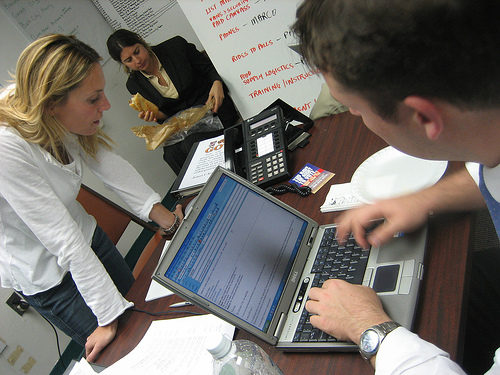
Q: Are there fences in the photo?
A: No, there are no fences.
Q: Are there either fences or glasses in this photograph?
A: No, there are no fences or glasses.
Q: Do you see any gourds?
A: No, there are no gourds.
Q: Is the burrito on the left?
A: Yes, the burrito is on the left of the image.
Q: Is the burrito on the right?
A: No, the burrito is on the left of the image.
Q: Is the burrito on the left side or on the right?
A: The burrito is on the left of the image.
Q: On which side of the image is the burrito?
A: The burrito is on the left of the image.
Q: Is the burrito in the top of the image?
A: Yes, the burrito is in the top of the image.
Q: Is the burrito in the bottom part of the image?
A: No, the burrito is in the top of the image.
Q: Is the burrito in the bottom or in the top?
A: The burrito is in the top of the image.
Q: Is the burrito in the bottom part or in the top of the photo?
A: The burrito is in the top of the image.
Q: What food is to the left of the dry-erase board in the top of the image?
A: The food is a burrito.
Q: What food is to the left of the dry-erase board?
A: The food is a burrito.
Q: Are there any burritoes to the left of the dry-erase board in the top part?
A: Yes, there is a burrito to the left of the dry-erase board.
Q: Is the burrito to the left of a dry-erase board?
A: Yes, the burrito is to the left of a dry-erase board.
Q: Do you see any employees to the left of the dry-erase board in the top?
A: Yes, there is an employee to the left of the dry-erase board.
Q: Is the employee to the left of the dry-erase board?
A: Yes, the employee is to the left of the dry-erase board.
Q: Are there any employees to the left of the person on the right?
A: Yes, there is an employee to the left of the person.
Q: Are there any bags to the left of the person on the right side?
A: No, there is an employee to the left of the person.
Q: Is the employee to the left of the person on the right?
A: Yes, the employee is to the left of the person.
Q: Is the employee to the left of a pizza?
A: No, the employee is to the left of the person.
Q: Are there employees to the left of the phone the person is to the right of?
A: Yes, there is an employee to the left of the telephone.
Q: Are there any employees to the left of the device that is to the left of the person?
A: Yes, there is an employee to the left of the telephone.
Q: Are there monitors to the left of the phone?
A: No, there is an employee to the left of the phone.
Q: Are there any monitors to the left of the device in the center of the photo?
A: No, there is an employee to the left of the phone.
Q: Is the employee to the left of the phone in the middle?
A: Yes, the employee is to the left of the phone.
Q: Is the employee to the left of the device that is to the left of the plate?
A: Yes, the employee is to the left of the phone.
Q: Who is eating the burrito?
A: The employee is eating the burrito.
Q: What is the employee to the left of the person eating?
A: The employee is eating a burrito.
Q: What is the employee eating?
A: The employee is eating a burrito.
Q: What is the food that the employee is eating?
A: The food is a burrito.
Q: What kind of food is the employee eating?
A: The employee is eating a burrito.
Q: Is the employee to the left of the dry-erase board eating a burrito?
A: Yes, the employee is eating a burrito.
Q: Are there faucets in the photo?
A: No, there are no faucets.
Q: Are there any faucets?
A: No, there are no faucets.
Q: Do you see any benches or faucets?
A: No, there are no faucets or benches.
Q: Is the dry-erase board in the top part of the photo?
A: Yes, the dry-erase board is in the top of the image.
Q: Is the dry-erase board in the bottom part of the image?
A: No, the dry-erase board is in the top of the image.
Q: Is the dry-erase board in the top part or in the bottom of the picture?
A: The dry-erase board is in the top of the image.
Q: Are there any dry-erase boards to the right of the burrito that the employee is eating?
A: Yes, there is a dry-erase board to the right of the burrito.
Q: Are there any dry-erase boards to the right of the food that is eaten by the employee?
A: Yes, there is a dry-erase board to the right of the burrito.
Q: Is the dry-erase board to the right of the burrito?
A: Yes, the dry-erase board is to the right of the burrito.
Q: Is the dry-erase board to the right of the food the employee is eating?
A: Yes, the dry-erase board is to the right of the burrito.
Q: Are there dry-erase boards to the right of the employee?
A: Yes, there is a dry-erase board to the right of the employee.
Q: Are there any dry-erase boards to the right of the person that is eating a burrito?
A: Yes, there is a dry-erase board to the right of the employee.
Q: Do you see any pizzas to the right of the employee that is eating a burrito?
A: No, there is a dry-erase board to the right of the employee.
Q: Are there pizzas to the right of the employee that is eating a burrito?
A: No, there is a dry-erase board to the right of the employee.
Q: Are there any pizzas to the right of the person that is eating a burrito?
A: No, there is a dry-erase board to the right of the employee.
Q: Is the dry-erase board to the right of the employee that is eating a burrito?
A: Yes, the dry-erase board is to the right of the employee.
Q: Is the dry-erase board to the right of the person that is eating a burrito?
A: Yes, the dry-erase board is to the right of the employee.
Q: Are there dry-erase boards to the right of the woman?
A: Yes, there is a dry-erase board to the right of the woman.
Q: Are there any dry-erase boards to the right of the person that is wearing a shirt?
A: Yes, there is a dry-erase board to the right of the woman.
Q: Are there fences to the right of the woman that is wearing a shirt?
A: No, there is a dry-erase board to the right of the woman.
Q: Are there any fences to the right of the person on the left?
A: No, there is a dry-erase board to the right of the woman.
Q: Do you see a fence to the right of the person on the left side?
A: No, there is a dry-erase board to the right of the woman.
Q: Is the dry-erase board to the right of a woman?
A: Yes, the dry-erase board is to the right of a woman.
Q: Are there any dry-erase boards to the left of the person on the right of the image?
A: Yes, there is a dry-erase board to the left of the person.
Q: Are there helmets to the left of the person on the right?
A: No, there is a dry-erase board to the left of the person.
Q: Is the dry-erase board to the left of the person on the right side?
A: Yes, the dry-erase board is to the left of the person.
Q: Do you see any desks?
A: Yes, there is a desk.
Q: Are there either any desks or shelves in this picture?
A: Yes, there is a desk.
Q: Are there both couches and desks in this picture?
A: No, there is a desk but no couches.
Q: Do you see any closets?
A: No, there are no closets.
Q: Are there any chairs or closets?
A: No, there are no closets or chairs.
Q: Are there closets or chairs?
A: No, there are no closets or chairs.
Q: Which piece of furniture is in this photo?
A: The piece of furniture is a desk.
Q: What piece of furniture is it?
A: The piece of furniture is a desk.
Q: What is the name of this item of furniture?
A: This is a desk.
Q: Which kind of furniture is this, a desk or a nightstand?
A: This is a desk.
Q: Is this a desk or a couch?
A: This is a desk.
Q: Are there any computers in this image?
A: Yes, there is a computer.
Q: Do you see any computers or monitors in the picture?
A: Yes, there is a computer.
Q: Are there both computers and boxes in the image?
A: No, there is a computer but no boxes.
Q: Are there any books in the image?
A: No, there are no books.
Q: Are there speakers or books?
A: No, there are no books or speakers.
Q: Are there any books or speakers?
A: No, there are no books or speakers.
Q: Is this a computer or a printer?
A: This is a computer.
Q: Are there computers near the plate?
A: Yes, there is a computer near the plate.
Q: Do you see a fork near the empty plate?
A: No, there is a computer near the plate.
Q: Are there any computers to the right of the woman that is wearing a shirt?
A: Yes, there is a computer to the right of the woman.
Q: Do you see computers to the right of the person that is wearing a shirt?
A: Yes, there is a computer to the right of the woman.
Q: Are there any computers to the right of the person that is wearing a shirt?
A: Yes, there is a computer to the right of the woman.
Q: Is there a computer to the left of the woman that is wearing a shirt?
A: No, the computer is to the right of the woman.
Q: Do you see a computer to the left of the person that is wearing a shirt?
A: No, the computer is to the right of the woman.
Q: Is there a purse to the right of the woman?
A: No, there is a computer to the right of the woman.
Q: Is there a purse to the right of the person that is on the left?
A: No, there is a computer to the right of the woman.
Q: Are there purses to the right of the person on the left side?
A: No, there is a computer to the right of the woman.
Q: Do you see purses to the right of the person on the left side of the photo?
A: No, there is a computer to the right of the woman.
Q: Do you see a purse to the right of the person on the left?
A: No, there is a computer to the right of the woman.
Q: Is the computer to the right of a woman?
A: Yes, the computer is to the right of a woman.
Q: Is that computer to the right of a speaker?
A: No, the computer is to the right of a woman.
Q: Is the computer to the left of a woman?
A: No, the computer is to the right of a woman.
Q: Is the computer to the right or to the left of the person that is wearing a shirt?
A: The computer is to the right of the woman.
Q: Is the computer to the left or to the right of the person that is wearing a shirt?
A: The computer is to the right of the woman.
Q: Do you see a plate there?
A: Yes, there is a plate.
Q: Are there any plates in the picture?
A: Yes, there is a plate.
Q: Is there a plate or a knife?
A: Yes, there is a plate.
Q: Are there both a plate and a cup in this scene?
A: No, there is a plate but no cups.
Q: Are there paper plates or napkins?
A: Yes, there is a paper plate.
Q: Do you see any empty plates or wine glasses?
A: Yes, there is an empty plate.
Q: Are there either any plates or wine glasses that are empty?
A: Yes, the plate is empty.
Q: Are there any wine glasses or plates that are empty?
A: Yes, the plate is empty.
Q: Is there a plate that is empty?
A: Yes, there is an empty plate.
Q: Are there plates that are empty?
A: Yes, there is a plate that is empty.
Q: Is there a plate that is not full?
A: Yes, there is a empty plate.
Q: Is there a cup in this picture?
A: No, there are no cups.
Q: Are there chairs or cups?
A: No, there are no cups or chairs.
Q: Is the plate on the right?
A: Yes, the plate is on the right of the image.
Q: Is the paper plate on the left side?
A: No, the plate is on the right of the image.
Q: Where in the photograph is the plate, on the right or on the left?
A: The plate is on the right of the image.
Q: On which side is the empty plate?
A: The plate is on the right of the image.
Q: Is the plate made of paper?
A: Yes, the plate is made of paper.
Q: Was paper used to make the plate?
A: Yes, the plate is made of paper.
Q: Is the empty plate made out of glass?
A: No, the plate is made of paper.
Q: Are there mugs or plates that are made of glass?
A: No, there is a plate but it is made of paper.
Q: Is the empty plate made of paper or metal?
A: The plate is made of paper.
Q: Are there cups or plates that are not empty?
A: No, there is a plate but it is empty.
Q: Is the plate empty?
A: Yes, the plate is empty.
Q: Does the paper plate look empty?
A: Yes, the plate is empty.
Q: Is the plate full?
A: No, the plate is empty.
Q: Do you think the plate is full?
A: No, the plate is empty.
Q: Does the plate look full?
A: No, the plate is empty.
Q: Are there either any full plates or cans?
A: No, there is a plate but it is empty.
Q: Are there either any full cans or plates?
A: No, there is a plate but it is empty.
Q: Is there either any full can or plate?
A: No, there is a plate but it is empty.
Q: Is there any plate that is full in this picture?
A: No, there is a plate but it is empty.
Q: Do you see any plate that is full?
A: No, there is a plate but it is empty.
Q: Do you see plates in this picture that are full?
A: No, there is a plate but it is empty.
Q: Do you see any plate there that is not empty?
A: No, there is a plate but it is empty.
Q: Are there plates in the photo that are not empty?
A: No, there is a plate but it is empty.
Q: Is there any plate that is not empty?
A: No, there is a plate but it is empty.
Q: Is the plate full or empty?
A: The plate is empty.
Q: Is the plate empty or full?
A: The plate is empty.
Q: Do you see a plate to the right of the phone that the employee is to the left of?
A: Yes, there is a plate to the right of the phone.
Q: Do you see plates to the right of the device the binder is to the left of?
A: Yes, there is a plate to the right of the phone.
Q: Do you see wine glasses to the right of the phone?
A: No, there is a plate to the right of the phone.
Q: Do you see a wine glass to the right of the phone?
A: No, there is a plate to the right of the phone.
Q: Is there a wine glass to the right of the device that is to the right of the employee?
A: No, there is a plate to the right of the phone.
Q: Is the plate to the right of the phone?
A: Yes, the plate is to the right of the phone.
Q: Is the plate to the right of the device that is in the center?
A: Yes, the plate is to the right of the phone.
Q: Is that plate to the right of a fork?
A: No, the plate is to the right of the phone.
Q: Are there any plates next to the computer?
A: Yes, there is a plate next to the computer.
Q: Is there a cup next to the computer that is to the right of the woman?
A: No, there is a plate next to the computer.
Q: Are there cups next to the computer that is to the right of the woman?
A: No, there is a plate next to the computer.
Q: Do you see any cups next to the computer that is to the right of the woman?
A: No, there is a plate next to the computer.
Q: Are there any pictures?
A: No, there are no pictures.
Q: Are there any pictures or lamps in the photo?
A: No, there are no pictures or lamps.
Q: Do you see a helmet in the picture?
A: No, there are no helmets.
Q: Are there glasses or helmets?
A: No, there are no helmets or glasses.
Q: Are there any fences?
A: No, there are no fences.